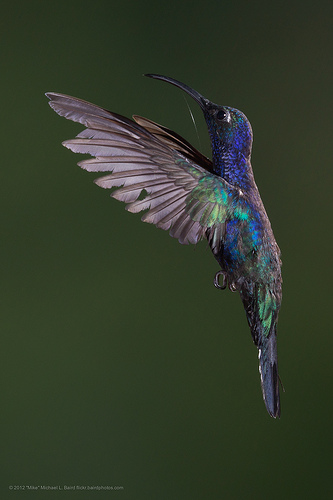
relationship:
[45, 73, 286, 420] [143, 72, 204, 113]
hummingbird has beak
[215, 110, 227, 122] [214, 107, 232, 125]
eye has lining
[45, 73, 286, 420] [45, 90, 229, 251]
hummingbird has wing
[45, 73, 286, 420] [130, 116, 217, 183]
hummingbird has wing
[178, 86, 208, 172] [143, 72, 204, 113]
spider web strand hanging from beak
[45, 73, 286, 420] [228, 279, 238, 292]
hummingbird has right foot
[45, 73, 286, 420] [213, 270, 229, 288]
hummingbird has left foot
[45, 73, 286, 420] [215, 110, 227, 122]
hummingbird has eye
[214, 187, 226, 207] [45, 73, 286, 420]
feather behind hummingbird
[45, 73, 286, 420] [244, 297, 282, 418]
hummingbird has tail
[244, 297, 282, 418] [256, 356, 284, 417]
tail has tip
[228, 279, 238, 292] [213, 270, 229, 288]
right foot touching left foot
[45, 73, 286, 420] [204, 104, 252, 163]
hummingbird has head